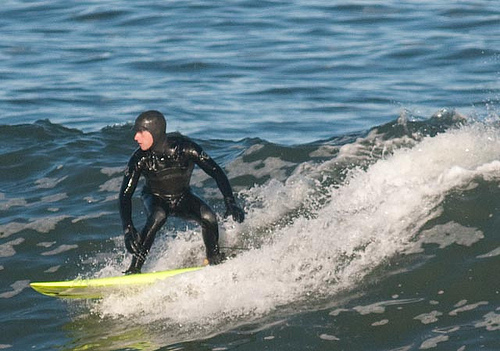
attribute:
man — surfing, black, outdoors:
[115, 110, 245, 275]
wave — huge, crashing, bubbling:
[1, 109, 498, 329]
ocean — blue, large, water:
[1, 0, 498, 351]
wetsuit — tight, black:
[118, 109, 245, 275]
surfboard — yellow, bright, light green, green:
[28, 261, 247, 301]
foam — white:
[1, 113, 498, 350]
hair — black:
[130, 124, 146, 132]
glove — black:
[222, 195, 245, 222]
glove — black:
[121, 221, 144, 256]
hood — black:
[134, 108, 166, 147]